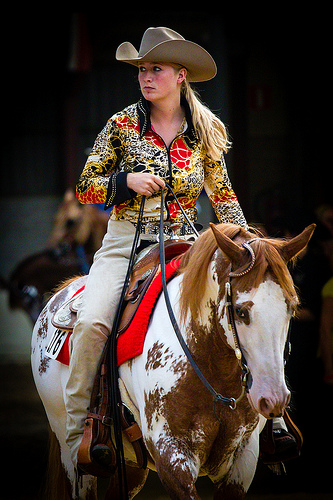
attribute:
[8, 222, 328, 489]
horse — brown, white 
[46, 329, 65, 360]
176 — contestant numbe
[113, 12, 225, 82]
hat — tan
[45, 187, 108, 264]
horses — blurry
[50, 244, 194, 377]
blanket — red 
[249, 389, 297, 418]
nose — pink 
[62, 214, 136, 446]
pants — white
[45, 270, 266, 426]
skin — brown 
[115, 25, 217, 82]
hat — beige cowboy 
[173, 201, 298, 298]
mane — brown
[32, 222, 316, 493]
horse — side , brown  , white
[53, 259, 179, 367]
blanket — red 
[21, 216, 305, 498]
horse — horse 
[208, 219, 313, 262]
ears — brown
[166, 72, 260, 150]
hair — blonde 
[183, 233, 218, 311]
mane — horse's 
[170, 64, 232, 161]
hair — blonde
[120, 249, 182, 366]
cloth — red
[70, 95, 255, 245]
shirt — woman's brightly colored , yellow, black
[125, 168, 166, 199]
hand — woman's 